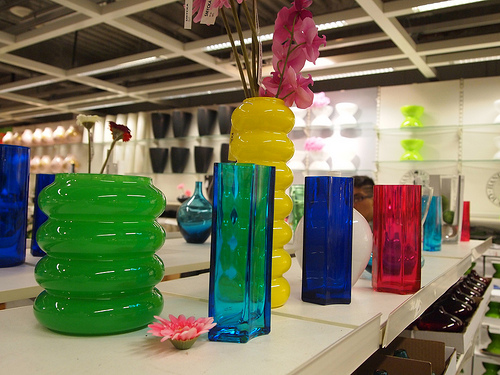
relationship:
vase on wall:
[150, 113, 170, 140] [112, 107, 253, 205]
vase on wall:
[166, 111, 189, 141] [112, 107, 253, 205]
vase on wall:
[194, 109, 215, 136] [112, 107, 253, 205]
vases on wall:
[301, 100, 373, 178] [277, 89, 375, 194]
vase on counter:
[40, 154, 158, 330] [14, 315, 156, 375]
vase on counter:
[215, 96, 296, 309] [212, 312, 332, 369]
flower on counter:
[147, 313, 218, 349] [83, 302, 284, 375]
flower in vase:
[79, 110, 97, 191] [64, 179, 156, 310]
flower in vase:
[101, 116, 133, 174] [29, 172, 166, 338]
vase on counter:
[292, 203, 381, 291] [55, 220, 458, 370]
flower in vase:
[252, 7, 333, 111] [226, 87, 303, 315]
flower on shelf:
[143, 308, 225, 352] [26, 268, 413, 368]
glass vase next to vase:
[207, 162, 276, 344] [218, 93, 306, 312]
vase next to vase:
[29, 172, 166, 338] [207, 158, 273, 348]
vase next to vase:
[370, 173, 424, 306] [291, 188, 378, 293]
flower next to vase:
[243, 3, 339, 110] [232, 93, 302, 323]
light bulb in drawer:
[429, 312, 469, 338] [433, 262, 483, 347]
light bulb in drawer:
[443, 293, 473, 316] [430, 256, 482, 355]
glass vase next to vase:
[207, 162, 276, 344] [371, 177, 425, 290]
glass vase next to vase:
[207, 162, 276, 344] [222, 93, 305, 325]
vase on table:
[29, 172, 166, 338] [28, 207, 437, 368]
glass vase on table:
[207, 162, 276, 344] [62, 178, 465, 370]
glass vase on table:
[207, 162, 276, 344] [102, 227, 482, 365]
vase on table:
[370, 184, 422, 295] [130, 199, 483, 370]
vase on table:
[412, 184, 453, 261] [127, 221, 483, 361]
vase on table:
[450, 194, 482, 254] [108, 239, 483, 372]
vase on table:
[171, 176, 222, 249] [1, 223, 477, 373]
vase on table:
[25, 155, 65, 254] [94, 282, 476, 373]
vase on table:
[1, 143, 31, 275] [32, 213, 481, 373]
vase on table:
[218, 93, 306, 312] [110, 167, 480, 358]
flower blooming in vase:
[286, 64, 314, 109] [228, 95, 293, 309]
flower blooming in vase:
[293, 17, 327, 66] [228, 95, 293, 309]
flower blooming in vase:
[282, 0, 312, 26] [228, 95, 293, 309]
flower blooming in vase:
[254, 70, 283, 93] [228, 95, 293, 309]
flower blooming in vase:
[182, 0, 207, 22] [228, 95, 293, 309]